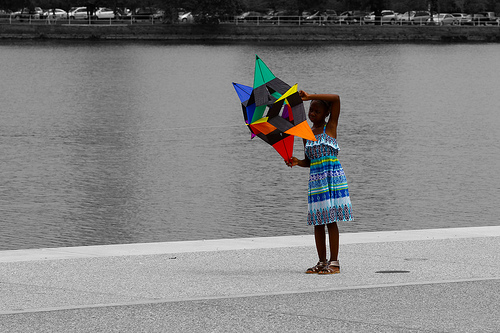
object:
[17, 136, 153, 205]
ripples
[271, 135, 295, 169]
triangle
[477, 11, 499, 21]
cars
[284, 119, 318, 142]
orange triangle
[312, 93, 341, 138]
arm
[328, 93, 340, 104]
elbow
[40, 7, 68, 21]
cars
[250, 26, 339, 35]
wall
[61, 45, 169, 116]
ripples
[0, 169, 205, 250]
water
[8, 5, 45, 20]
car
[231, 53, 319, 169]
kite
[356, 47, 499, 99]
water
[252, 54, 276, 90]
triangle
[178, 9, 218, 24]
cars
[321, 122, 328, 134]
strap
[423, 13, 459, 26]
cars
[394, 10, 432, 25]
cars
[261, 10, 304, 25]
cars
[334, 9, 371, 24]
cars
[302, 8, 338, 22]
cars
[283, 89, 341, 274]
girl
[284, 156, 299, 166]
hand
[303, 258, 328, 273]
sandal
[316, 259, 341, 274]
sandal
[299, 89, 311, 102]
hand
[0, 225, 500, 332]
sidewalk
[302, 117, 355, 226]
dress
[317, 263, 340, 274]
feet